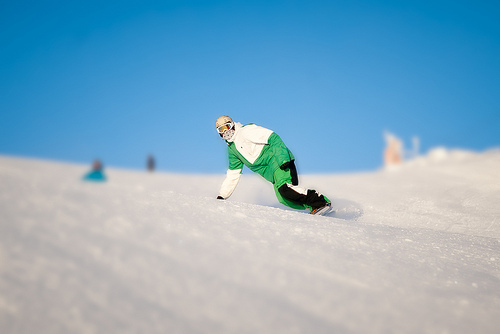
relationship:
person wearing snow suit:
[216, 114, 332, 216] [218, 121, 331, 211]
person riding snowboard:
[216, 114, 332, 216] [307, 200, 331, 216]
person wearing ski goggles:
[216, 114, 332, 216] [216, 122, 235, 135]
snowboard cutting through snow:
[307, 200, 331, 216] [0, 147, 499, 333]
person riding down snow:
[216, 114, 332, 216] [0, 147, 499, 333]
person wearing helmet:
[216, 114, 332, 216] [216, 116, 233, 131]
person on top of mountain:
[216, 114, 332, 216] [0, 145, 499, 331]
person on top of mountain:
[80, 158, 107, 182] [0, 145, 499, 331]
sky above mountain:
[1, 0, 499, 176] [0, 145, 499, 331]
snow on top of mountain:
[0, 147, 499, 333] [0, 145, 499, 331]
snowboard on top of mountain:
[307, 200, 331, 216] [0, 145, 499, 331]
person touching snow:
[216, 114, 332, 216] [0, 147, 499, 333]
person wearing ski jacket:
[216, 114, 332, 216] [220, 121, 296, 199]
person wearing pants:
[216, 114, 332, 216] [270, 164, 329, 213]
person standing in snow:
[80, 158, 107, 182] [0, 147, 499, 333]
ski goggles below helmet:
[216, 122, 235, 135] [216, 116, 233, 131]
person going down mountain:
[216, 114, 332, 216] [0, 145, 499, 331]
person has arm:
[216, 114, 332, 216] [216, 147, 243, 200]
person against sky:
[216, 114, 332, 216] [1, 0, 499, 176]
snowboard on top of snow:
[307, 200, 331, 216] [0, 147, 499, 333]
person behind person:
[80, 158, 107, 182] [216, 114, 332, 216]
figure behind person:
[146, 153, 157, 170] [216, 114, 332, 216]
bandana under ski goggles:
[221, 130, 234, 141] [216, 122, 235, 135]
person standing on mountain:
[80, 158, 107, 182] [0, 145, 499, 331]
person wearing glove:
[216, 114, 332, 216] [280, 163, 291, 171]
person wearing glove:
[216, 114, 332, 216] [216, 195, 224, 200]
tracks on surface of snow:
[5, 210, 346, 333] [0, 147, 499, 333]